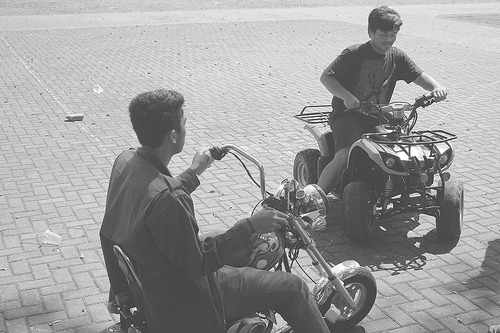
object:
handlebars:
[343, 90, 449, 135]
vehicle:
[293, 90, 466, 243]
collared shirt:
[99, 146, 257, 332]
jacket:
[99, 147, 256, 333]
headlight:
[302, 183, 332, 219]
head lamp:
[301, 183, 331, 219]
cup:
[40, 228, 63, 245]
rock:
[65, 113, 84, 121]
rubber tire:
[342, 181, 375, 243]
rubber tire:
[436, 173, 463, 245]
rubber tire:
[293, 147, 322, 189]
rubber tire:
[312, 259, 378, 332]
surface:
[0, 2, 500, 333]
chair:
[292, 104, 333, 124]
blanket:
[292, 91, 466, 243]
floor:
[209, 163, 275, 190]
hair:
[367, 5, 403, 39]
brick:
[100, 28, 257, 69]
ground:
[26, 155, 71, 192]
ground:
[1, 0, 498, 332]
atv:
[292, 92, 464, 243]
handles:
[205, 127, 331, 249]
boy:
[97, 88, 330, 333]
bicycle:
[98, 142, 378, 333]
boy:
[316, 5, 448, 196]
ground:
[12, 49, 120, 144]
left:
[3, 0, 249, 330]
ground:
[8, 14, 476, 182]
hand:
[191, 144, 291, 235]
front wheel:
[311, 259, 377, 332]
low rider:
[99, 88, 330, 333]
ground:
[5, 10, 115, 330]